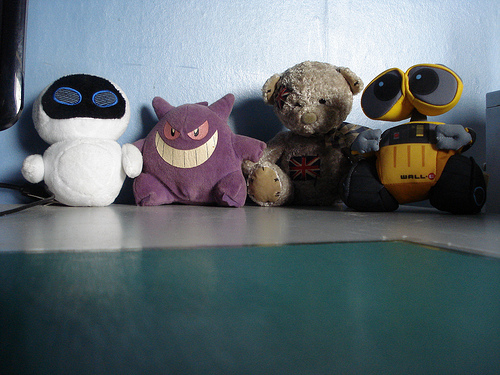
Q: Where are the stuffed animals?
A: Against the wall.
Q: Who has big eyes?
A: Stuffed animal on right.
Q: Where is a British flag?
A: On brown teddy bear.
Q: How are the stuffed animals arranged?
A: In a row.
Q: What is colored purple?
A: The second stuffed animal.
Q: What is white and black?
A: Stuffed animal on left.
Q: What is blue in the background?
A: The backdrop.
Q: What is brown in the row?
A: A brown teddy bear.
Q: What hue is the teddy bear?
A: Brown.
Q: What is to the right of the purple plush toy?
A: A brown teddy bear.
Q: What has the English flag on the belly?
A: A brown teddy bear.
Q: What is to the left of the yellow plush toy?
A: A brown teddy bear.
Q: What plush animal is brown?
A: The teddy bear.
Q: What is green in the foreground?
A: The table.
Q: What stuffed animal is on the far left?
A: The white one.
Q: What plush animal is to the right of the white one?
A: The purple stuffed animal.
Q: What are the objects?
A: Stuffed animals.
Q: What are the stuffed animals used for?
A: Toys.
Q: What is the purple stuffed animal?
A: A pokemon.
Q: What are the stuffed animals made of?
A: Fabric.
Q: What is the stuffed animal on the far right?
A: Wall e.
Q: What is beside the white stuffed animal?
A: A cord.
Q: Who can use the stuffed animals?
A: A child.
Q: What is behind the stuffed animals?
A: A wall.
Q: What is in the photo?
A: Four toys.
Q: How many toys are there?
A: Four.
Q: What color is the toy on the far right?
A: Yellow.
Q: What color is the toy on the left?
A: White.